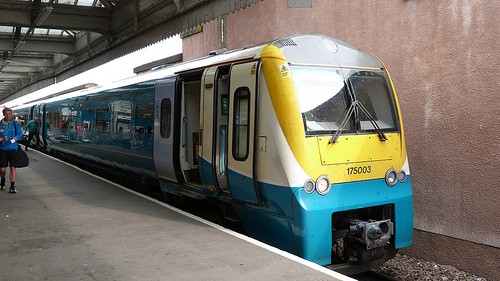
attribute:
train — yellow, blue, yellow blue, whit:
[84, 28, 422, 255]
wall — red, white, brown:
[438, 28, 494, 145]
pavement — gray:
[91, 211, 202, 253]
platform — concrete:
[108, 212, 270, 267]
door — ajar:
[151, 76, 238, 196]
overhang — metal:
[17, 4, 74, 78]